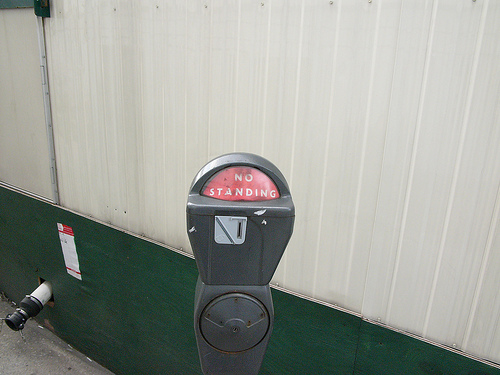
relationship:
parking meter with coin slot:
[184, 152, 295, 372] [233, 217, 243, 242]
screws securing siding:
[54, 0, 479, 13] [1, 0, 496, 364]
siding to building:
[1, 0, 496, 364] [36, 12, 493, 364]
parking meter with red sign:
[184, 152, 295, 372] [190, 158, 287, 207]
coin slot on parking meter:
[214, 216, 246, 245] [184, 152, 295, 372]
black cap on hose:
[0, 299, 51, 342] [3, 278, 52, 333]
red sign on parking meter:
[199, 162, 279, 202] [184, 152, 295, 372]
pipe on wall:
[25, 7, 70, 209] [7, 15, 499, 372]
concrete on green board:
[5, 303, 127, 373] [13, 202, 478, 372]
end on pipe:
[3, 294, 40, 332] [30, 281, 51, 308]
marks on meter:
[245, 207, 276, 229] [140, 142, 335, 365]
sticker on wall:
[47, 215, 85, 287] [0, 12, 194, 313]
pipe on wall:
[31, 7, 68, 209] [90, 18, 440, 128]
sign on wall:
[54, 222, 79, 284] [315, 54, 470, 187]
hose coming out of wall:
[3, 278, 52, 333] [7, 15, 499, 372]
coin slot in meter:
[214, 216, 246, 245] [184, 154, 278, 372]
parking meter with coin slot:
[184, 152, 295, 372] [228, 214, 247, 249]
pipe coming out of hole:
[3, 274, 59, 344] [38, 260, 65, 311]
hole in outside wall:
[38, 260, 65, 311] [59, 16, 287, 133]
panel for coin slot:
[196, 208, 260, 265] [231, 213, 250, 240]